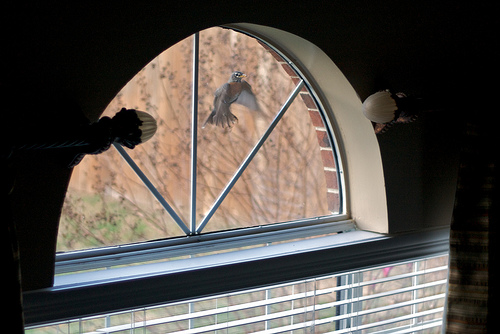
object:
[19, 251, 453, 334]
blinds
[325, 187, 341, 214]
brick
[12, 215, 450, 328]
trim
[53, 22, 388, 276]
half circle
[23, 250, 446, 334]
window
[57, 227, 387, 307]
sil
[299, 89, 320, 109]
building brick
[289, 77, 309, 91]
building brick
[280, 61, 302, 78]
building brick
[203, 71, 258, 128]
bird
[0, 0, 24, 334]
curtain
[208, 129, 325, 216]
tree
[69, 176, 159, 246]
tree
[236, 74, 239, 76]
eye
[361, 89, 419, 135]
light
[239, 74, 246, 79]
beak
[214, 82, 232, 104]
wing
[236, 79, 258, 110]
wing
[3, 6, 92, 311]
dark wall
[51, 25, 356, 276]
window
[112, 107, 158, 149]
light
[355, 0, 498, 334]
curtain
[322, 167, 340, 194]
brick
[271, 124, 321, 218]
branches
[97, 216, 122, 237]
leaves